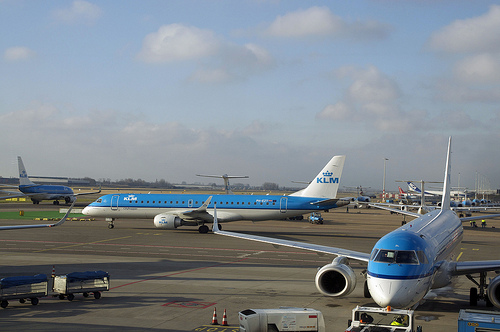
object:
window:
[394, 249, 419, 265]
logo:
[316, 169, 338, 183]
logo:
[17, 168, 27, 176]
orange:
[208, 317, 217, 324]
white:
[213, 309, 218, 316]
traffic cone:
[220, 306, 228, 324]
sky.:
[0, 1, 499, 198]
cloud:
[227, 3, 395, 42]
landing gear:
[106, 221, 114, 229]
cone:
[209, 306, 217, 324]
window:
[370, 248, 395, 266]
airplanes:
[80, 155, 352, 232]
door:
[277, 194, 287, 211]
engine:
[313, 265, 355, 300]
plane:
[209, 137, 499, 309]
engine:
[152, 212, 204, 227]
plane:
[0, 153, 103, 202]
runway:
[0, 185, 499, 332]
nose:
[361, 269, 431, 309]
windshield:
[368, 250, 415, 265]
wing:
[209, 204, 366, 265]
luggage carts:
[51, 269, 110, 301]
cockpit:
[370, 241, 430, 268]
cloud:
[41, 0, 106, 29]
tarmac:
[0, 205, 499, 332]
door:
[111, 191, 121, 210]